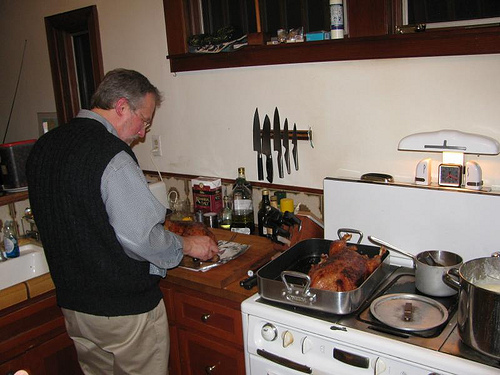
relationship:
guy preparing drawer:
[23, 68, 218, 375] [173, 289, 242, 344]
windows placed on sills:
[170, 11, 363, 56] [190, 37, 490, 69]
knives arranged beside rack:
[246, 116, 286, 166] [239, 124, 324, 150]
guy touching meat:
[23, 68, 218, 375] [157, 208, 224, 261]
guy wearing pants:
[23, 68, 218, 375] [55, 300, 173, 373]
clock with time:
[436, 159, 466, 189] [442, 168, 462, 184]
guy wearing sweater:
[23, 68, 218, 375] [23, 108, 171, 320]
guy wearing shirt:
[23, 68, 218, 375] [68, 106, 190, 283]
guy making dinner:
[23, 68, 218, 375] [156, 213, 222, 267]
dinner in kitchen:
[156, 213, 222, 267] [2, 0, 498, 372]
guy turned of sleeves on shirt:
[23, 68, 218, 375] [71, 104, 184, 269]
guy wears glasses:
[23, 68, 218, 375] [139, 116, 154, 133]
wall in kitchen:
[173, 86, 236, 154] [2, 0, 498, 372]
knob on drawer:
[201, 311, 209, 320] [173, 287, 243, 344]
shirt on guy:
[102, 157, 164, 247] [43, 68, 165, 370]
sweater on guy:
[35, 140, 126, 310] [43, 68, 165, 370]